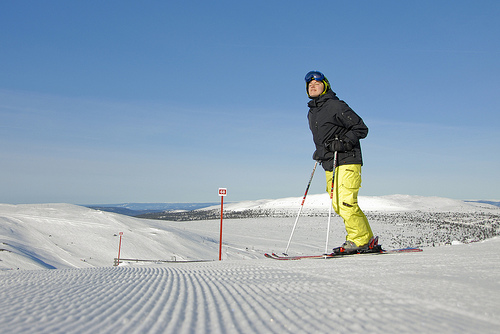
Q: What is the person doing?
A: Skiing.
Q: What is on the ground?
A: Snow.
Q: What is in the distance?
A: A snow covered mountain.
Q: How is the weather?
A: Cold.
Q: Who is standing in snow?
A: The woman.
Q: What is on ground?
A: Snow.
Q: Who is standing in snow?
A: The woman.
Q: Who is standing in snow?
A: The woman.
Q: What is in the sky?
A: Clouds.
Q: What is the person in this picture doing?
A: Skiing.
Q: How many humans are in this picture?
A: One.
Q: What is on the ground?
A: Snow.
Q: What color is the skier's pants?
A: Yellow.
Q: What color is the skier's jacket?
A: Black.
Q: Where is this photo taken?
A: Mountain.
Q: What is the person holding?
A: Poles.